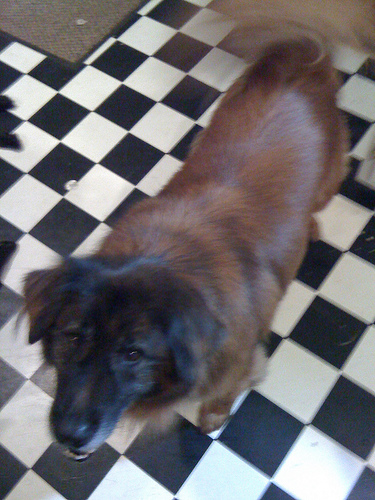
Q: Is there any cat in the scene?
A: No, there are no cats.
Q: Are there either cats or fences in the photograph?
A: No, there are no cats or fences.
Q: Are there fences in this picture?
A: No, there are no fences.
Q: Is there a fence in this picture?
A: No, there are no fences.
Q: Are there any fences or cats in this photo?
A: No, there are no fences or cats.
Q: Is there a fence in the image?
A: No, there are no fences.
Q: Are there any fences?
A: No, there are no fences.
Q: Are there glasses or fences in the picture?
A: No, there are no fences or glasses.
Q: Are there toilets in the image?
A: No, there are no toilets.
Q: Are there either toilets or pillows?
A: No, there are no toilets or pillows.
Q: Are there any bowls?
A: No, there are no bowls.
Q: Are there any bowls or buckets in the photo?
A: No, there are no bowls or buckets.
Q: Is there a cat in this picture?
A: No, there are no cats.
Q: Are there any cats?
A: No, there are no cats.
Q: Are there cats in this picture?
A: No, there are no cats.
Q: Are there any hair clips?
A: No, there are no hair clips.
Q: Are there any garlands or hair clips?
A: No, there are no hair clips or garlands.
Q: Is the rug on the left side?
A: Yes, the rug is on the left of the image.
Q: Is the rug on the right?
A: No, the rug is on the left of the image.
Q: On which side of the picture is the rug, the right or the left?
A: The rug is on the left of the image.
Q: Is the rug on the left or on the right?
A: The rug is on the left of the image.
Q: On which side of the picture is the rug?
A: The rug is on the left of the image.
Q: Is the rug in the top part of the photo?
A: Yes, the rug is in the top of the image.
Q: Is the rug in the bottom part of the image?
A: No, the rug is in the top of the image.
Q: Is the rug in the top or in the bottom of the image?
A: The rug is in the top of the image.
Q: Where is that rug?
A: The rug is on the floor.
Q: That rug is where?
A: The rug is on the floor.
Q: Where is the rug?
A: The rug is on the floor.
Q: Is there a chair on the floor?
A: No, there is a rug on the floor.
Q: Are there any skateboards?
A: No, there are no skateboards.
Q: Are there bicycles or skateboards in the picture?
A: No, there are no skateboards or bicycles.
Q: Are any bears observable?
A: No, there are no bears.